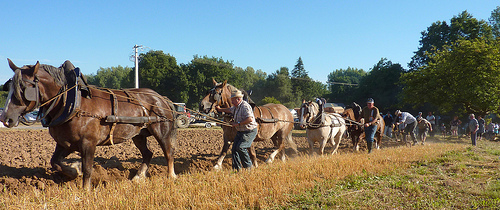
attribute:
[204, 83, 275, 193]
man — guiding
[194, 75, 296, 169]
horse — light brown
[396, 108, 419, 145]
man — bent down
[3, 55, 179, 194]
horses — plowing up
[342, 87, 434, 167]
man — bent over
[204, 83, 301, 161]
horse — brown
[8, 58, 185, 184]
lead horse — dark, brown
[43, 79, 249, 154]
horse — brown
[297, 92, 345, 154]
horse — white, brown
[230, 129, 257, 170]
jeans — blue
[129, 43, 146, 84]
electrical pole — wood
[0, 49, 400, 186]
horse — connected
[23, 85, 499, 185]
horses — connnected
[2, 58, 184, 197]
horse — walking, dark brown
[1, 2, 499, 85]
sky — clear